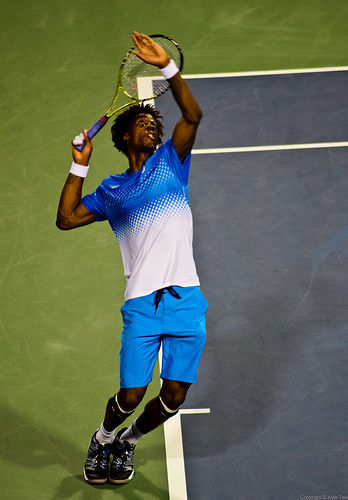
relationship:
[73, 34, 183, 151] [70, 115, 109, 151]
tennis racket has handle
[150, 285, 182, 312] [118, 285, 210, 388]
drawstring around shorts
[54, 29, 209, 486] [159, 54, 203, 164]
man has arm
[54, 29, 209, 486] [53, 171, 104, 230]
man has arm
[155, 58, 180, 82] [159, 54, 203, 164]
wristband around arm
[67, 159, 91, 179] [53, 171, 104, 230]
wristband around arm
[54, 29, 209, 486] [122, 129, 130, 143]
man has ear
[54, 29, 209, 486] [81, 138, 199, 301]
man wearing shirt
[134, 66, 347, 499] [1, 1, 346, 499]
lines on top of tennis court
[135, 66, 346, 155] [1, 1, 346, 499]
lines near back of tennis court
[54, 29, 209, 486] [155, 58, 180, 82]
man wearing wristband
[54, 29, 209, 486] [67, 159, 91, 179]
man wearing wristband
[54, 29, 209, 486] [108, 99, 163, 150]
man has hair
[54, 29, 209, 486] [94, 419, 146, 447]
man wearing socks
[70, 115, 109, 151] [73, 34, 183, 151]
handle on bottom of tennis racket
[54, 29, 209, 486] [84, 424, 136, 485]
man wearing shoes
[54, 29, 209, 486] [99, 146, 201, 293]
man has torso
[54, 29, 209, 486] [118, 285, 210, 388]
man wearing shorts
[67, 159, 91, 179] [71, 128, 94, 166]
wristband under handle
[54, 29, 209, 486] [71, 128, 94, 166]
man has handle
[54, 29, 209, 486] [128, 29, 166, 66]
man has left hand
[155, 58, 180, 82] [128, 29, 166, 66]
wristband under left hand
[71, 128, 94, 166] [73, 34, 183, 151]
handle grasping tennis racket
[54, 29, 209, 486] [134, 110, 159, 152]
man has face